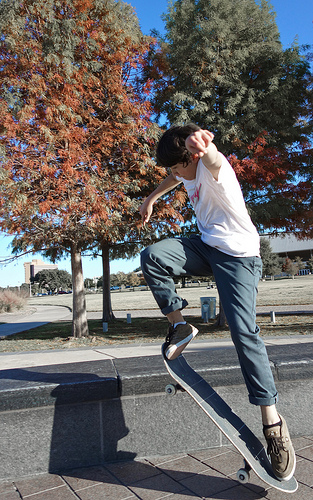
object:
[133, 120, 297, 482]
boy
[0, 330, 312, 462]
road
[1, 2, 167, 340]
trees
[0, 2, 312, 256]
sky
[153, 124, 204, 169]
hair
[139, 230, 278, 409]
trouser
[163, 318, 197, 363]
shoe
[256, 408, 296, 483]
shoe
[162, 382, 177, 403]
wheel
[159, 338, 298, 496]
board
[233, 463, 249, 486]
wheel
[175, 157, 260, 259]
shirt